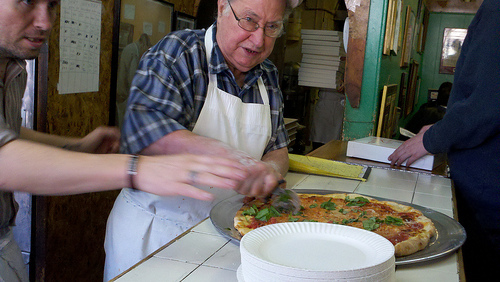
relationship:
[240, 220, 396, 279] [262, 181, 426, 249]
plates next to pizza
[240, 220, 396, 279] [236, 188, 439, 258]
plates next to pizza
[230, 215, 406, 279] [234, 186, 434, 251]
plates next to pizza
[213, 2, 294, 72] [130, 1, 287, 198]
head on person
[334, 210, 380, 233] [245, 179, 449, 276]
leaf on pizza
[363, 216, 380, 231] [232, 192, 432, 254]
leaf on pizza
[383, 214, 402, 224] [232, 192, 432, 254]
leaf on pizza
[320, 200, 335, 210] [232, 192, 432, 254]
leaf on pizza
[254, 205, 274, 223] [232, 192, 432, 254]
leaf on pizza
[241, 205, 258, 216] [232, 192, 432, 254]
leaf on pizza